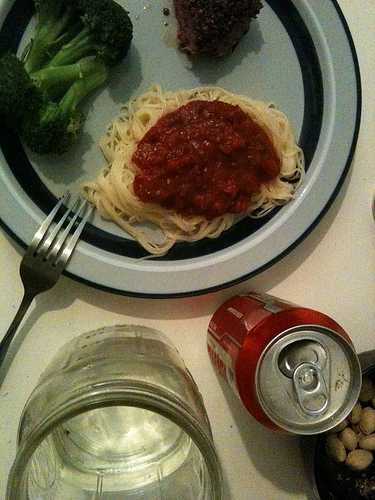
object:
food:
[79, 83, 306, 264]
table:
[0, 0, 362, 297]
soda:
[219, 304, 351, 437]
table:
[311, 249, 365, 302]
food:
[5, 7, 282, 153]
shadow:
[210, 357, 319, 500]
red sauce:
[132, 99, 280, 221]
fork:
[0, 190, 94, 366]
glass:
[6, 324, 224, 499]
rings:
[0, 0, 324, 261]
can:
[207, 292, 363, 435]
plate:
[0, 0, 363, 300]